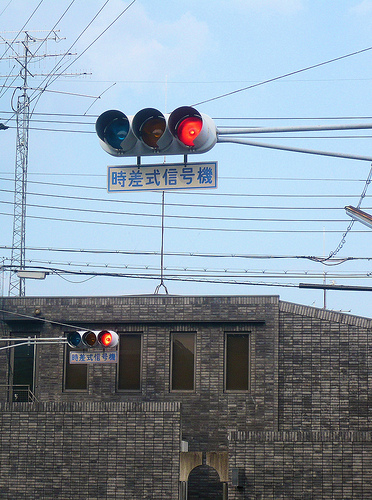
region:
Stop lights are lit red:
[63, 104, 217, 345]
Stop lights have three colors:
[64, 103, 214, 347]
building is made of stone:
[1, 295, 370, 498]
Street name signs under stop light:
[68, 163, 221, 364]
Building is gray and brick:
[0, 294, 370, 497]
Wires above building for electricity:
[1, 0, 370, 297]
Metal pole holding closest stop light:
[215, 125, 370, 169]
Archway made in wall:
[178, 449, 229, 496]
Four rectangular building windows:
[61, 328, 256, 400]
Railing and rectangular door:
[1, 331, 41, 403]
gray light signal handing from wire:
[87, 108, 208, 150]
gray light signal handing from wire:
[161, 105, 201, 146]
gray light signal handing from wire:
[61, 326, 118, 345]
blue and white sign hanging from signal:
[100, 162, 220, 192]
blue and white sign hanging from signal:
[55, 348, 124, 367]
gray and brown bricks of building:
[11, 401, 173, 490]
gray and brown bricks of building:
[189, 399, 360, 489]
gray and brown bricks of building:
[255, 314, 361, 476]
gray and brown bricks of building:
[120, 305, 264, 407]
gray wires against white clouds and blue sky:
[6, 6, 336, 93]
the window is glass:
[228, 310, 291, 409]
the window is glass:
[208, 349, 252, 439]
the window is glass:
[210, 300, 286, 462]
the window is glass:
[193, 332, 270, 430]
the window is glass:
[205, 285, 265, 385]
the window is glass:
[226, 354, 249, 393]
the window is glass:
[179, 257, 268, 424]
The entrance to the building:
[183, 458, 235, 497]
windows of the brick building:
[215, 327, 260, 396]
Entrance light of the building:
[175, 431, 194, 459]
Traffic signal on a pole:
[87, 109, 242, 155]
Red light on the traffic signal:
[169, 106, 215, 151]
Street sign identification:
[97, 165, 242, 196]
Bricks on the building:
[90, 425, 112, 457]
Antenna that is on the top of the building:
[1, 21, 50, 259]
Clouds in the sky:
[131, 27, 233, 59]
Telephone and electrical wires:
[27, 178, 105, 226]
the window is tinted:
[219, 324, 270, 422]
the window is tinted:
[216, 305, 282, 458]